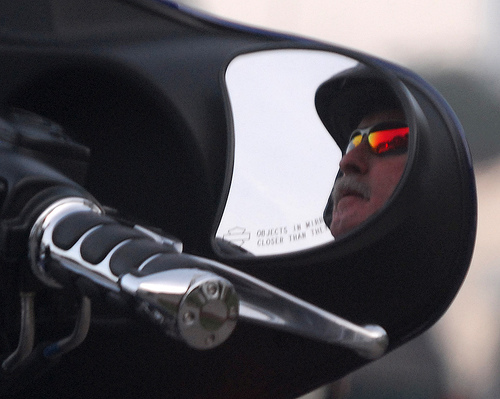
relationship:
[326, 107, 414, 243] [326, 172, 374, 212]
man has a mustache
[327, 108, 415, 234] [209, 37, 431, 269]
face reflected in mirror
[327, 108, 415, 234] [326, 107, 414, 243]
face of man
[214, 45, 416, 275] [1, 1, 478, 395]
mirror on motorcycle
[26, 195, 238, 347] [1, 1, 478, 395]
handle on motorcycle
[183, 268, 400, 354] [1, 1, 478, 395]
brakes for motorcycle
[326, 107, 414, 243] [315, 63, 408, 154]
man wearing helmet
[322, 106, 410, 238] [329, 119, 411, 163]
man wearing sunglasses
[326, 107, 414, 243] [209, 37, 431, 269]
man reflection in mirror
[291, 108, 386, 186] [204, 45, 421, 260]
part of a mirror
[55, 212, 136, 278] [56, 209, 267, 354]
part of an handle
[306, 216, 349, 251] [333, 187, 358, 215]
edge of a mirror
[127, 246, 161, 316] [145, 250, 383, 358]
part of a brake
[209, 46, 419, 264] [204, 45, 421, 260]
edge of a mirror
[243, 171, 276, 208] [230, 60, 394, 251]
part of a mirror